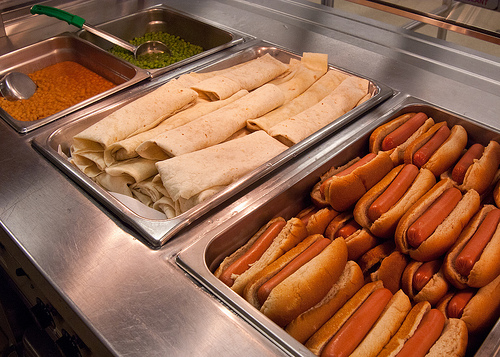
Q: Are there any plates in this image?
A: No, there are no plates.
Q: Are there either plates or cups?
A: No, there are no plates or cups.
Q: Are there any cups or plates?
A: No, there are no plates or cups.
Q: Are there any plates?
A: No, there are no plates.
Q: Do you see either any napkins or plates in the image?
A: No, there are no plates or napkins.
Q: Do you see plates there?
A: No, there are no plates.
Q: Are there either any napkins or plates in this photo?
A: No, there are no plates or napkins.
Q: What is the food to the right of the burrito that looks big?
A: The food is a bun.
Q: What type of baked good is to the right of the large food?
A: The food is a bun.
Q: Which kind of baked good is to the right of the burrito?
A: The food is a bun.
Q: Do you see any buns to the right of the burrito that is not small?
A: Yes, there is a bun to the right of the burrito.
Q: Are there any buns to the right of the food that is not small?
A: Yes, there is a bun to the right of the burrito.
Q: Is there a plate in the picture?
A: No, there are no plates.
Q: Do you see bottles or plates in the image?
A: No, there are no plates or bottles.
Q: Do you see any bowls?
A: No, there are no bowls.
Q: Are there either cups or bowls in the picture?
A: No, there are no bowls or cups.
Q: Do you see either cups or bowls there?
A: No, there are no bowls or cups.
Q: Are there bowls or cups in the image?
A: No, there are no bowls or cups.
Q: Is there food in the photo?
A: Yes, there is food.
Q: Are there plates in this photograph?
A: No, there are no plates.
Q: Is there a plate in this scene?
A: No, there are no plates.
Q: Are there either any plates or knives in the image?
A: No, there are no plates or knives.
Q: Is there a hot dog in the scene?
A: Yes, there is a hot dog.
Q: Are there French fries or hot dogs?
A: Yes, there is a hot dog.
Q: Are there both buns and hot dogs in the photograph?
A: Yes, there are both a hot dog and a bun.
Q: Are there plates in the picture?
A: No, there are no plates.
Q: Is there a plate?
A: No, there are no plates.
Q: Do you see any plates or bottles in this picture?
A: No, there are no plates or bottles.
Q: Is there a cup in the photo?
A: No, there are no cups.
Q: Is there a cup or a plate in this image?
A: No, there are no cups or plates.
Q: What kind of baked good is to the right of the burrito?
A: The food is a bun.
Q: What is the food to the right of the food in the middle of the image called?
A: The food is a bun.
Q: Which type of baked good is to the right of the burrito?
A: The food is a bun.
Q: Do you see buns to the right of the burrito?
A: Yes, there is a bun to the right of the burrito.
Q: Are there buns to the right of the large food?
A: Yes, there is a bun to the right of the burrito.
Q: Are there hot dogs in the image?
A: Yes, there is a hot dog.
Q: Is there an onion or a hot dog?
A: Yes, there is a hot dog.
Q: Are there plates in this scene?
A: No, there are no plates.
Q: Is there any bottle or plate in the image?
A: No, there are no plates or bottles.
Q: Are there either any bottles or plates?
A: No, there are no plates or bottles.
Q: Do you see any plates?
A: No, there are no plates.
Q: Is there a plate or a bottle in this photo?
A: No, there are no plates or bottles.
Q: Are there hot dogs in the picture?
A: Yes, there is a hot dog.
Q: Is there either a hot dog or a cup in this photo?
A: Yes, there is a hot dog.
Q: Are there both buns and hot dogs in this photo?
A: Yes, there are both a hot dog and a bun.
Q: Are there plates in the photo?
A: No, there are no plates.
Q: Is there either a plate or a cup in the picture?
A: No, there are no plates or cups.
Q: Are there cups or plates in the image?
A: No, there are no plates or cups.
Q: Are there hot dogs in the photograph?
A: Yes, there is a hot dog.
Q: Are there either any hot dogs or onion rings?
A: Yes, there is a hot dog.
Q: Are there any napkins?
A: No, there are no napkins.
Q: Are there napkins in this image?
A: No, there are no napkins.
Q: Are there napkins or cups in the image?
A: No, there are no napkins or cups.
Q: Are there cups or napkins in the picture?
A: No, there are no napkins or cups.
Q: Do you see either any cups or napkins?
A: No, there are no napkins or cups.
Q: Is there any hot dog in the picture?
A: Yes, there is a hot dog.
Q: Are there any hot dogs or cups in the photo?
A: Yes, there is a hot dog.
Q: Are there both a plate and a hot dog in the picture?
A: No, there is a hot dog but no plates.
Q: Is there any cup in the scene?
A: No, there are no cups.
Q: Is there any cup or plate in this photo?
A: No, there are no cups or plates.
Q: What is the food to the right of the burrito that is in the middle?
A: The food is a hot dog.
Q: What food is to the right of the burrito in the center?
A: The food is a hot dog.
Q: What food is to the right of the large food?
A: The food is a hot dog.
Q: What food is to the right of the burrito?
A: The food is a hot dog.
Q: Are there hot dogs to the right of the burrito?
A: Yes, there is a hot dog to the right of the burrito.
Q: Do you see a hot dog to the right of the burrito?
A: Yes, there is a hot dog to the right of the burrito.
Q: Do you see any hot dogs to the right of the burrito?
A: Yes, there is a hot dog to the right of the burrito.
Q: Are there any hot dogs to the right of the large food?
A: Yes, there is a hot dog to the right of the burrito.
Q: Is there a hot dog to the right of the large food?
A: Yes, there is a hot dog to the right of the burrito.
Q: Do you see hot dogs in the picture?
A: Yes, there is a hot dog.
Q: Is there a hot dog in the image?
A: Yes, there is a hot dog.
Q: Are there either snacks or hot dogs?
A: Yes, there is a hot dog.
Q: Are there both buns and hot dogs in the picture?
A: Yes, there are both a hot dog and a bun.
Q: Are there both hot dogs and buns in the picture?
A: Yes, there are both a hot dog and a bun.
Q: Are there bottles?
A: No, there are no bottles.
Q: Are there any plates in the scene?
A: No, there are no plates.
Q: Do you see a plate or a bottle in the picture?
A: No, there are no plates or bottles.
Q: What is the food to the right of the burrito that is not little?
A: The food is a bun.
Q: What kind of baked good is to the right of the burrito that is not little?
A: The food is a bun.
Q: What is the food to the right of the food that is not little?
A: The food is a bun.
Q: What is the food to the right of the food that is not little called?
A: The food is a bun.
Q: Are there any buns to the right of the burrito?
A: Yes, there is a bun to the right of the burrito.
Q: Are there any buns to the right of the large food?
A: Yes, there is a bun to the right of the burrito.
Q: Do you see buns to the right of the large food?
A: Yes, there is a bun to the right of the burrito.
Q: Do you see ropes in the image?
A: No, there are no ropes.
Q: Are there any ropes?
A: No, there are no ropes.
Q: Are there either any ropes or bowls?
A: No, there are no ropes or bowls.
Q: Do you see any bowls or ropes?
A: No, there are no ropes or bowls.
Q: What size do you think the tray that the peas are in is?
A: The tray is small.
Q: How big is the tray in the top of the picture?
A: The tray is small.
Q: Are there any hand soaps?
A: No, there are no hand soaps.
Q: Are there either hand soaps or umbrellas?
A: No, there are no hand soaps or umbrellas.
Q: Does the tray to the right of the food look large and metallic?
A: Yes, the tray is large and metallic.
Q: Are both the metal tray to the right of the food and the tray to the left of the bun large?
A: Yes, both the tray and the tray are large.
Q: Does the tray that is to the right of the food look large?
A: Yes, the tray is large.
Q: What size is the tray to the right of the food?
A: The tray is large.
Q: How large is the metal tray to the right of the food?
A: The tray is large.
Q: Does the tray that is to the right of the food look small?
A: No, the tray is large.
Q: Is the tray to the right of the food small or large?
A: The tray is large.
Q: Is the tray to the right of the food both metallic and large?
A: Yes, the tray is metallic and large.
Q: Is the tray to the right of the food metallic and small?
A: No, the tray is metallic but large.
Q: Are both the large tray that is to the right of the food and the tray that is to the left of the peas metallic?
A: Yes, both the tray and the tray are metallic.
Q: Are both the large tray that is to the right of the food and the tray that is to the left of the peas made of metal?
A: Yes, both the tray and the tray are made of metal.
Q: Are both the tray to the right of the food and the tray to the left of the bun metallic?
A: Yes, both the tray and the tray are metallic.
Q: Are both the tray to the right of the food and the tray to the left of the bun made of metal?
A: Yes, both the tray and the tray are made of metal.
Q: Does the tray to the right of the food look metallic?
A: Yes, the tray is metallic.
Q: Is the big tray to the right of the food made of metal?
A: Yes, the tray is made of metal.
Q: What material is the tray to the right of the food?
A: The tray is made of metal.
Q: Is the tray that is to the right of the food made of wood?
A: No, the tray is made of metal.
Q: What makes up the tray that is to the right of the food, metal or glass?
A: The tray is made of metal.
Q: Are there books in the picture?
A: No, there are no books.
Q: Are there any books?
A: No, there are no books.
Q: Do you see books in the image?
A: No, there are no books.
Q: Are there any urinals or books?
A: No, there are no books or urinals.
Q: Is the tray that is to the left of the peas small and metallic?
A: Yes, the tray is small and metallic.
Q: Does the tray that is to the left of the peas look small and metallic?
A: Yes, the tray is small and metallic.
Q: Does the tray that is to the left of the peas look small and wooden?
A: No, the tray is small but metallic.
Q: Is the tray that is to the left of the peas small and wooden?
A: No, the tray is small but metallic.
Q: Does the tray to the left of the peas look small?
A: Yes, the tray is small.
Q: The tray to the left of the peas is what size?
A: The tray is small.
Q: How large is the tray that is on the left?
A: The tray is small.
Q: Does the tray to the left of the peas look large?
A: No, the tray is small.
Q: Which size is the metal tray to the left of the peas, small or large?
A: The tray is small.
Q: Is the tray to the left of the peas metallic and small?
A: Yes, the tray is metallic and small.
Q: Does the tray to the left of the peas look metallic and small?
A: Yes, the tray is metallic and small.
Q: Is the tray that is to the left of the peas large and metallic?
A: No, the tray is metallic but small.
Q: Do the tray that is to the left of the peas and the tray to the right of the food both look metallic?
A: Yes, both the tray and the tray are metallic.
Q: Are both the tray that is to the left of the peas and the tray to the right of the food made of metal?
A: Yes, both the tray and the tray are made of metal.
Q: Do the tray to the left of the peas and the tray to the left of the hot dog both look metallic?
A: Yes, both the tray and the tray are metallic.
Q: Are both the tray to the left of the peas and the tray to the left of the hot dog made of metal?
A: Yes, both the tray and the tray are made of metal.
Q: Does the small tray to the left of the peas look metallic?
A: Yes, the tray is metallic.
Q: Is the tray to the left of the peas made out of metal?
A: Yes, the tray is made of metal.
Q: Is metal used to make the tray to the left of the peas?
A: Yes, the tray is made of metal.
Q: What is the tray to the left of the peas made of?
A: The tray is made of metal.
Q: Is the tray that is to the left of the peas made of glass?
A: No, the tray is made of metal.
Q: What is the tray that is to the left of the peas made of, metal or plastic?
A: The tray is made of metal.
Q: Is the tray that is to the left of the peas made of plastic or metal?
A: The tray is made of metal.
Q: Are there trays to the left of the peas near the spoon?
A: Yes, there is a tray to the left of the peas.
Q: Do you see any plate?
A: No, there are no plates.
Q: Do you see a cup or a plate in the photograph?
A: No, there are no plates or cups.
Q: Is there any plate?
A: No, there are no plates.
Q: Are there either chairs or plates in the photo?
A: No, there are no plates or chairs.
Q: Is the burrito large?
A: Yes, the burrito is large.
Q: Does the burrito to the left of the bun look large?
A: Yes, the burrito is large.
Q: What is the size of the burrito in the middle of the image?
A: The burrito is large.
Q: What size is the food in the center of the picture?
A: The burrito is large.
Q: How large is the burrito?
A: The burrito is large.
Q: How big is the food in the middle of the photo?
A: The burrito is large.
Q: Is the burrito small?
A: No, the burrito is large.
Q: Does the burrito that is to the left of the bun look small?
A: No, the burrito is large.